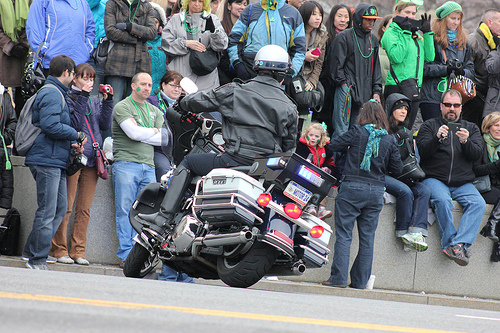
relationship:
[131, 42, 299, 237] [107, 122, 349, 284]
patrolman riding motorcycle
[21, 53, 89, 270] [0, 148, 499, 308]
man standing in front of wall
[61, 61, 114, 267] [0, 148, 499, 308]
people standing in front of wall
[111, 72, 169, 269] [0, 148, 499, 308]
man standing in front of wall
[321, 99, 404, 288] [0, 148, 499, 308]
people standing in front of wall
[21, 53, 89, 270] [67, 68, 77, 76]
man wearing glasses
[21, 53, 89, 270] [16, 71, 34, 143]
man carrying backpack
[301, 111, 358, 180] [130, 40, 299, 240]
child looking at patrolman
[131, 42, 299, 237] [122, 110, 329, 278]
patrolman riding motorcycle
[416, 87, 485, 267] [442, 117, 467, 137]
man holding cellphone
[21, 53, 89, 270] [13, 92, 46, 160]
man carrying backpack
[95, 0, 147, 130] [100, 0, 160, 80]
woman wearing coat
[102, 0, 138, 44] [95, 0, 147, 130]
arm belonging to woman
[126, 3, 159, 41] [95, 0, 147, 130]
arm belonging to woman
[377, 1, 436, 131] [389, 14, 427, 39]
woman wearing scarf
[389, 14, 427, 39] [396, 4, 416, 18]
scarf covering face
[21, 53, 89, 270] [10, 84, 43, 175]
man carrying backpack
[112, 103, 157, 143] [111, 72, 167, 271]
arm belonging to man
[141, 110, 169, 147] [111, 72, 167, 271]
arm belonging to man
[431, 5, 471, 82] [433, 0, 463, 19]
woman wearing cap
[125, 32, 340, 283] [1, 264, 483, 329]
motorcycle turning around on street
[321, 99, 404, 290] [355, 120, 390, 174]
people wearing scarf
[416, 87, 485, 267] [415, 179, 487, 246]
man wearing jeans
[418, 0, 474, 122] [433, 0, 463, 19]
woman wearing cap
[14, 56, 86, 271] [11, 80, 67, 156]
man carrying backpack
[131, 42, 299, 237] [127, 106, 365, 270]
patrolman riding motorcycle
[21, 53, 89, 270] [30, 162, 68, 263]
man wearing jeans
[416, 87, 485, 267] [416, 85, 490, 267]
man holding cellphone